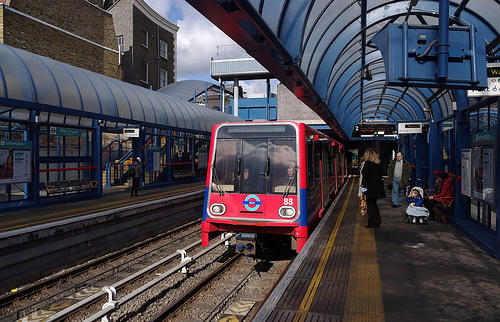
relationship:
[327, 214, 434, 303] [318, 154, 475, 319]
shadows on sidewalk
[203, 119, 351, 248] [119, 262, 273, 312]
train on track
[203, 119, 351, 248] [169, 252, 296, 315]
train on track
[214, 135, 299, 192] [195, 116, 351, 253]
windshield on train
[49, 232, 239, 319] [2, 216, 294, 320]
rails by tracks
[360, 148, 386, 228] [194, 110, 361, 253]
lady waiting for train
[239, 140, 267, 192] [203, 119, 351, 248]
window on train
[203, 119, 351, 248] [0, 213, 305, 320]
train on track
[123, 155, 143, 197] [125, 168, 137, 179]
person carrying purse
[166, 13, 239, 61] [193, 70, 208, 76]
clouds in sky